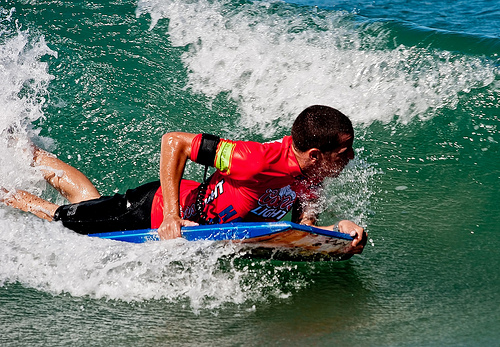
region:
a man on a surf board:
[2, 91, 401, 312]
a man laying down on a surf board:
[5, 75, 396, 306]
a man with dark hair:
[282, 84, 369, 165]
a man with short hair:
[279, 109, 371, 176]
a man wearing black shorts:
[13, 163, 155, 268]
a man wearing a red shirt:
[191, 119, 311, 266]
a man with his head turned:
[282, 112, 370, 199]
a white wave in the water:
[131, 14, 455, 100]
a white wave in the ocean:
[84, 24, 405, 94]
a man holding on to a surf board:
[122, 200, 365, 287]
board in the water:
[62, 212, 382, 276]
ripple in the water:
[301, 273, 373, 310]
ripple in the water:
[135, 305, 160, 322]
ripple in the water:
[368, 280, 398, 305]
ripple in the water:
[433, 213, 481, 245]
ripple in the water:
[100, 310, 132, 330]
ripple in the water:
[51, 284, 90, 317]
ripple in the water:
[418, 133, 453, 156]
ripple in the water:
[405, 125, 434, 147]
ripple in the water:
[88, 283, 115, 308]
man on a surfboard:
[8, 76, 409, 262]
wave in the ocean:
[81, 263, 136, 293]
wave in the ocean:
[206, 285, 249, 310]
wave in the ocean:
[15, 240, 50, 265]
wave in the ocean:
[421, 95, 455, 119]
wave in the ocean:
[405, 215, 434, 241]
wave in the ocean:
[385, 265, 425, 300]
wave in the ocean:
[406, 20, 468, 55]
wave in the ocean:
[163, 18, 223, 46]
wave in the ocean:
[12, 37, 77, 81]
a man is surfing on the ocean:
[3, 110, 367, 252]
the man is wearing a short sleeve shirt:
[162, 127, 309, 244]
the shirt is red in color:
[152, 130, 319, 264]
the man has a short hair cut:
[291, 102, 353, 157]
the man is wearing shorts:
[56, 175, 158, 241]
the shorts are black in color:
[54, 169, 163, 246]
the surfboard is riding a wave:
[94, 215, 354, 265]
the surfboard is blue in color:
[100, 218, 352, 268]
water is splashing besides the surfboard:
[7, 195, 282, 321]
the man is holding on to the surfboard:
[152, 130, 371, 249]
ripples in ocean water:
[91, 121, 141, 159]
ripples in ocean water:
[62, 51, 116, 105]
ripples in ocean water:
[30, 300, 85, 343]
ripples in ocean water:
[245, 291, 292, 339]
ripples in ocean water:
[328, 284, 373, 328]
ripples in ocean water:
[412, 294, 480, 340]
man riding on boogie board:
[34, 91, 384, 279]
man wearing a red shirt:
[155, 101, 307, 230]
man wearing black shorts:
[55, 161, 176, 237]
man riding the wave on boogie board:
[41, 44, 393, 299]